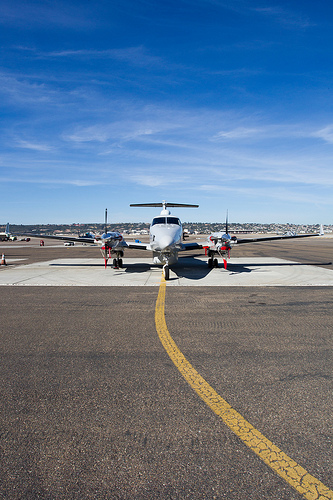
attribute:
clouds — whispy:
[132, 155, 330, 192]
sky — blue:
[0, 2, 332, 224]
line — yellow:
[156, 274, 330, 500]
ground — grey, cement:
[0, 236, 332, 499]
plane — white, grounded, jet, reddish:
[13, 201, 322, 279]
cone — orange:
[0, 249, 8, 268]